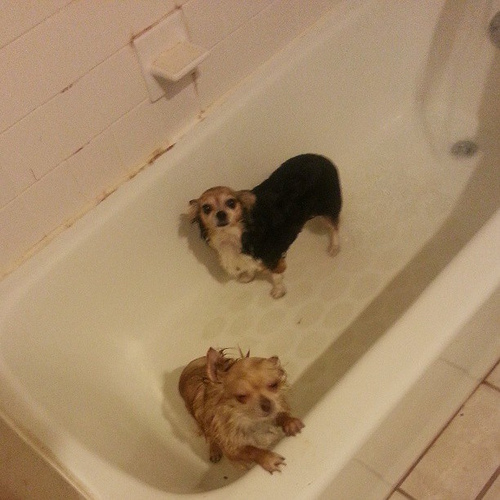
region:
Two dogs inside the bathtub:
[161, 138, 366, 480]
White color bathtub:
[386, 165, 452, 267]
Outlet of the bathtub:
[436, 120, 482, 167]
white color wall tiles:
[26, 26, 105, 131]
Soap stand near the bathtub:
[141, 39, 208, 86]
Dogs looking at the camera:
[177, 192, 290, 417]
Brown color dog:
[167, 351, 325, 470]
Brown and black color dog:
[190, 186, 366, 281]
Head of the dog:
[183, 180, 270, 238]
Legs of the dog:
[258, 233, 378, 298]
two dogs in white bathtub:
[142, 153, 392, 475]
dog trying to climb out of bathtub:
[157, 347, 304, 472]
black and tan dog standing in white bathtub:
[170, 150, 372, 292]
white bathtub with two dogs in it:
[22, 20, 499, 491]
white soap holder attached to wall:
[126, 10, 211, 95]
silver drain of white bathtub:
[442, 135, 474, 158]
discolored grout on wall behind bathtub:
[10, 18, 265, 234]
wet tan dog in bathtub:
[171, 348, 318, 476]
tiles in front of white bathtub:
[391, 381, 498, 499]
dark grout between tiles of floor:
[372, 385, 499, 495]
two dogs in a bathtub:
[157, 142, 378, 481]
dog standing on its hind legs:
[173, 348, 323, 478]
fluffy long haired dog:
[155, 349, 322, 481]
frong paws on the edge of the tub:
[253, 408, 313, 474]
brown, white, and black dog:
[182, 149, 364, 308]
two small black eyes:
[197, 196, 239, 214]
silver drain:
[440, 135, 478, 162]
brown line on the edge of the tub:
[130, 140, 179, 167]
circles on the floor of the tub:
[198, 189, 422, 406]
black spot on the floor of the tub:
[291, 312, 307, 330]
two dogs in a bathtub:
[9, 20, 499, 498]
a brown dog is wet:
[153, 334, 334, 481]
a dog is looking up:
[176, 143, 358, 308]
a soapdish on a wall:
[128, 6, 215, 101]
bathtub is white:
[0, 0, 499, 496]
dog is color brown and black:
[179, 148, 355, 299]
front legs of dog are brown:
[228, 262, 294, 303]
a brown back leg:
[317, 227, 349, 257]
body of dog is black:
[247, 144, 347, 256]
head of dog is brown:
[177, 183, 257, 242]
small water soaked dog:
[191, 153, 347, 298]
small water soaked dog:
[171, 348, 311, 475]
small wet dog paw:
[258, 453, 288, 476]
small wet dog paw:
[280, 415, 305, 432]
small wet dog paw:
[205, 446, 226, 463]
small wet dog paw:
[326, 240, 341, 252]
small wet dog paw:
[270, 285, 286, 299]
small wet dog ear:
[202, 345, 226, 383]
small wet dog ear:
[269, 356, 281, 368]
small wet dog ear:
[236, 190, 257, 211]